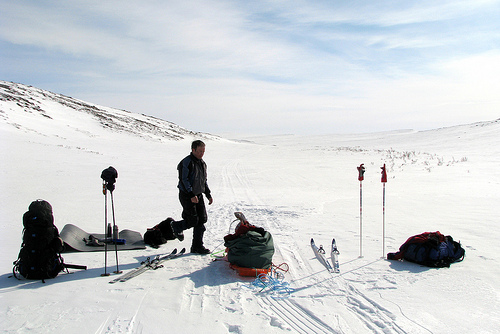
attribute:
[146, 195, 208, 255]
pants — dark 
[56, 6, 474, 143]
sky — is blue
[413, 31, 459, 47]
clouds — white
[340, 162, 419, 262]
poles — ski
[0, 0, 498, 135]
clouds — thin, white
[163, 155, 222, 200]
coat — black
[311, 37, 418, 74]
sky — blue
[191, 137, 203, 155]
hair — dark 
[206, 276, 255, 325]
track — ski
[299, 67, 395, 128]
clouds — white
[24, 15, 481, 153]
sky — blue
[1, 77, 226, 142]
land — elevated 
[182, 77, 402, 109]
sky — blue and white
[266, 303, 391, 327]
track — ski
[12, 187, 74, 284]
pack — Largest , black 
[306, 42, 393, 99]
clouds — white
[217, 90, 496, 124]
clouds — white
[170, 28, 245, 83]
clouds — white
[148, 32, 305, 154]
clouds — white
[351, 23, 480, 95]
sky — blue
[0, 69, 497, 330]
snow — white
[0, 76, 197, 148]
ground — brown 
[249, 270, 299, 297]
rope — blue 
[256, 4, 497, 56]
cloud — white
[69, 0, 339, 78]
cloud — white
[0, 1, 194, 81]
cloud — white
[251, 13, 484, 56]
cloud — white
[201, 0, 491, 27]
cloud — white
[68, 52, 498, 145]
cloud — white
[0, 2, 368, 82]
cloud — white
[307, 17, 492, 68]
cloud — white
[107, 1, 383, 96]
cloud — white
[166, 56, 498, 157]
cloud — white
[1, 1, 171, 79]
cloud — white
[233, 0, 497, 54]
cloud — white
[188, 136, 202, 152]
hair — Dark 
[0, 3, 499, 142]
sky — blue, cloudy 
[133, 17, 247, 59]
cloud — is white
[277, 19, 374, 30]
sky — is blue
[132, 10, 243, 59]
cloud — is white